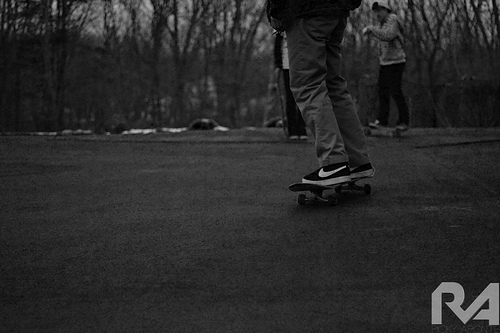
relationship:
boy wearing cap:
[360, 1, 413, 131] [370, 0, 398, 15]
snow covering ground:
[121, 122, 190, 137] [66, 148, 246, 249]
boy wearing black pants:
[360, 1, 413, 131] [372, 59, 408, 128]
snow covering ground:
[121, 122, 192, 136] [44, 125, 199, 143]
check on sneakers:
[315, 161, 349, 181] [288, 149, 365, 189]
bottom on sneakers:
[299, 177, 355, 189] [302, 159, 374, 187]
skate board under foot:
[289, 174, 379, 205] [300, 164, 352, 183]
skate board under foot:
[289, 174, 379, 205] [350, 161, 376, 179]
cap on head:
[370, 0, 398, 15] [369, 8, 393, 19]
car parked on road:
[188, 114, 222, 134] [13, 112, 499, 128]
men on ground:
[241, 0, 443, 202] [0, 133, 286, 333]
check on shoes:
[315, 161, 349, 181] [301, 163, 352, 185]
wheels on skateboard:
[299, 188, 340, 205] [289, 179, 375, 205]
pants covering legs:
[292, 32, 386, 202] [300, 77, 359, 163]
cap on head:
[370, 0, 392, 8] [368, 1, 400, 25]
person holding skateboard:
[269, 30, 307, 146] [269, 69, 286, 136]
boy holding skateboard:
[360, 1, 413, 131] [367, 121, 417, 138]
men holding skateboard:
[261, 0, 375, 202] [292, 169, 379, 206]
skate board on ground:
[287, 170, 377, 206] [141, 190, 411, 300]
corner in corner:
[426, 277, 500, 333] [409, 277, 495, 325]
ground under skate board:
[0, 133, 286, 333] [287, 170, 377, 206]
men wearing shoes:
[261, 0, 375, 202] [303, 160, 373, 185]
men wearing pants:
[261, 0, 375, 202] [286, 12, 372, 169]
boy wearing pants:
[360, 1, 413, 131] [376, 60, 411, 127]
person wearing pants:
[269, 30, 307, 146] [282, 68, 307, 134]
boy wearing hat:
[362, 1, 413, 131] [366, 1, 410, 38]